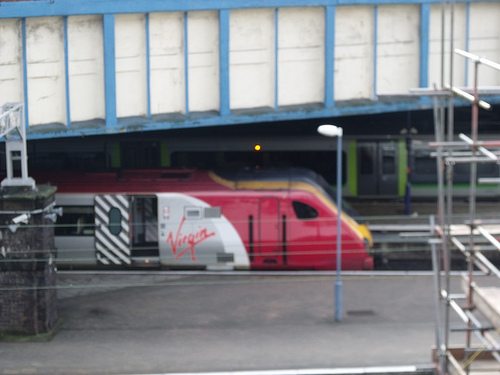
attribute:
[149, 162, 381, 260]
train — red, green, silver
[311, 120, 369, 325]
pole — silver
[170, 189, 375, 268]
car — pink, yellow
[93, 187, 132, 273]
door — striped, black, white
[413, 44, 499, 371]
scaffolding — silver metal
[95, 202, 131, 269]
door — striped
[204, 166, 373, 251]
stripe — yellow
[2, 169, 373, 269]
train — white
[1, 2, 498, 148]
overpass — blue and white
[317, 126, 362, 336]
pole — silver 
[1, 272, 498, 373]
platform — grey concrete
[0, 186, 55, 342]
brick post — red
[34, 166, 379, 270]
train — silver 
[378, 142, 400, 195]
door — gray